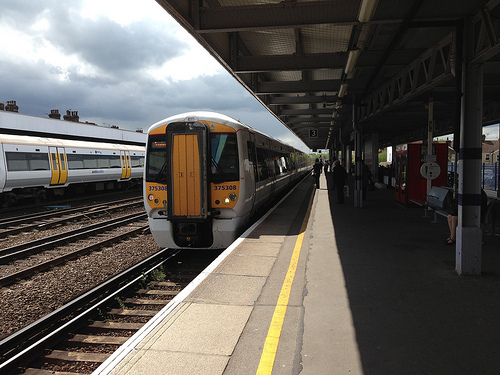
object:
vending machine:
[392, 137, 449, 206]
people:
[312, 155, 325, 192]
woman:
[441, 183, 461, 244]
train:
[142, 112, 320, 250]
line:
[257, 185, 320, 374]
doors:
[47, 147, 69, 186]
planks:
[33, 276, 181, 371]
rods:
[23, 245, 167, 353]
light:
[222, 195, 232, 206]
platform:
[95, 158, 500, 375]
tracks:
[0, 181, 218, 375]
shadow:
[243, 172, 318, 239]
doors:
[166, 118, 204, 221]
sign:
[307, 125, 320, 138]